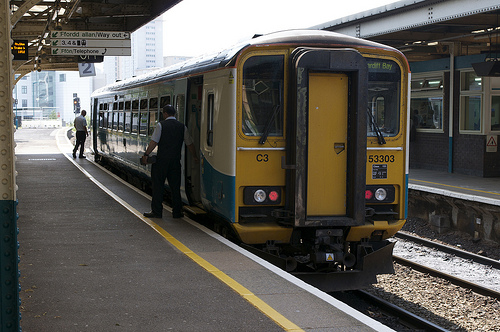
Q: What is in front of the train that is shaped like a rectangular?
A: Door.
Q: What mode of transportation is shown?
A: Train.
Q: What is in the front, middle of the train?
A: Door.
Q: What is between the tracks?
A: Gravel.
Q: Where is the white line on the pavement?
A: Beside the train.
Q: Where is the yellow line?
A: Left of the white line.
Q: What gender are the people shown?
A: Male.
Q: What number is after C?
A: 3.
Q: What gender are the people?
A: Male.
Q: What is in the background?
A: Building.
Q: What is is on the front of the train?
A: Windshield.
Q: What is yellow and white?
A: Train.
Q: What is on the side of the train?
A: Windows.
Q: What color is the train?
A: Yellow.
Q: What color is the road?
A: Black.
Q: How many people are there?
A: Two.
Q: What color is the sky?
A: Grey.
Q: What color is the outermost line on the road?
A: White.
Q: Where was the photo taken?
A: Train stop.